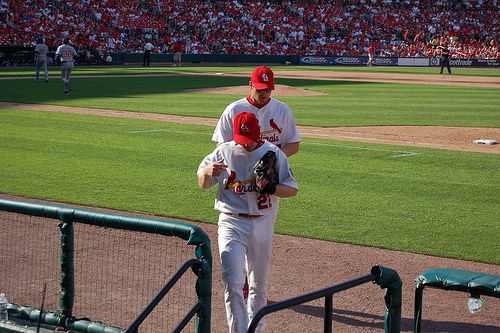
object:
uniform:
[194, 138, 301, 329]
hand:
[249, 172, 278, 195]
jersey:
[196, 139, 300, 217]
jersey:
[211, 94, 305, 150]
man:
[209, 65, 304, 161]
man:
[194, 111, 300, 332]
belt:
[237, 213, 265, 220]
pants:
[215, 209, 276, 331]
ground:
[418, 138, 432, 155]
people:
[391, 25, 416, 42]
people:
[139, 38, 160, 65]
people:
[254, 21, 271, 36]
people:
[189, 40, 204, 57]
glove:
[251, 150, 280, 196]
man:
[54, 37, 81, 96]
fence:
[95, 55, 309, 97]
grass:
[7, 107, 187, 211]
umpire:
[437, 44, 453, 75]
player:
[54, 37, 80, 96]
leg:
[216, 240, 250, 331]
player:
[33, 37, 50, 83]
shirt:
[194, 136, 302, 218]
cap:
[250, 65, 275, 92]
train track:
[129, 119, 423, 171]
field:
[1, 59, 493, 330]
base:
[337, 119, 499, 158]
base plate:
[471, 138, 498, 147]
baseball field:
[0, 63, 497, 258]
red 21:
[256, 194, 269, 210]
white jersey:
[194, 140, 302, 215]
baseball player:
[208, 65, 304, 290]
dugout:
[6, 192, 498, 329]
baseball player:
[197, 111, 297, 330]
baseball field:
[8, 64, 498, 331]